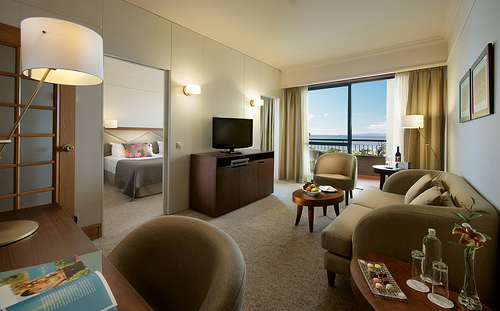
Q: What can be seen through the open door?
A: Bed.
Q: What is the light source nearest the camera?
A: Lamp.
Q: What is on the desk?
A: Magazine.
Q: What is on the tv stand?
A: Tv.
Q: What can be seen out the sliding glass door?
A: Ocean.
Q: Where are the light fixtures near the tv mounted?
A: Wall.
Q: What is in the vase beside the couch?
A: Flower.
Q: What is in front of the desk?
A: Chair.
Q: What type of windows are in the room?
A: Sliding door.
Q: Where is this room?
A: Hotel.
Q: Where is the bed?
A: In the bedroom.